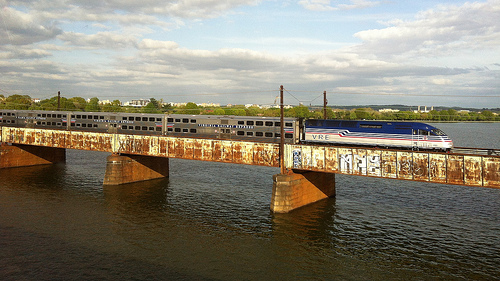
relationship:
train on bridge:
[224, 103, 464, 177] [305, 148, 417, 186]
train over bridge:
[224, 103, 464, 177] [305, 148, 417, 186]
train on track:
[224, 103, 464, 177] [455, 143, 495, 164]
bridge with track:
[305, 148, 417, 186] [455, 143, 495, 164]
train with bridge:
[224, 103, 464, 177] [305, 148, 417, 186]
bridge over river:
[305, 148, 417, 186] [63, 180, 243, 275]